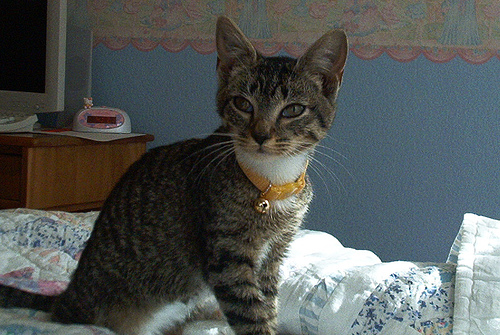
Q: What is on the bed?
A: Cat.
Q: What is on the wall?
A: Painting.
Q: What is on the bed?
A: Comforter.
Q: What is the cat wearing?
A: BELL.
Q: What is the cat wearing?
A: Collar.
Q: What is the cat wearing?
A: Yellow collar.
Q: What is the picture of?
A: A cat.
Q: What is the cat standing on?
A: A bed.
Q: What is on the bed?
A: A quilt.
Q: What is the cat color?
A: Grey, black and white.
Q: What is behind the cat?
A: A wall.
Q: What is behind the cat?
A: A table.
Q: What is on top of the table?
A: A clock.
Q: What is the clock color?
A: Pink and white.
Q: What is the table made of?
A: Wood.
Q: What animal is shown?
A: Caty.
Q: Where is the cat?
A: On the bed.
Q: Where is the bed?
A: In the room.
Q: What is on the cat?
A: A collar.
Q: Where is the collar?
A: On the cat.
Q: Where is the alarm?
A: On the desk.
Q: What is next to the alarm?
A: A tv.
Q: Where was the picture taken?
A: In a bedroom.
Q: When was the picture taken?
A: Daytime.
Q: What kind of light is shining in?
A: Sunlight.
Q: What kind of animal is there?
A: A cat.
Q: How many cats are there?
A: One.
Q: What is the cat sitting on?
A: A bed.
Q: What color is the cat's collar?
A: Yellow.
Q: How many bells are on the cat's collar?
A: One.